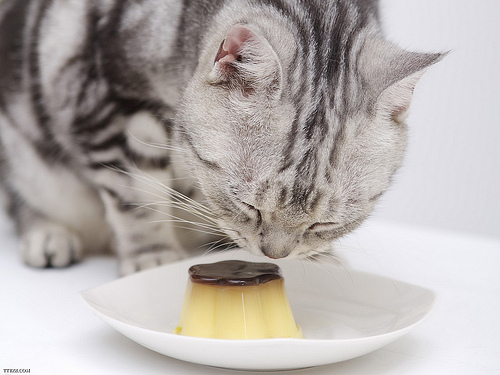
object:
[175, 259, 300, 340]
cake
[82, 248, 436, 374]
plate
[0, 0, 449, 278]
cat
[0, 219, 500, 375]
table